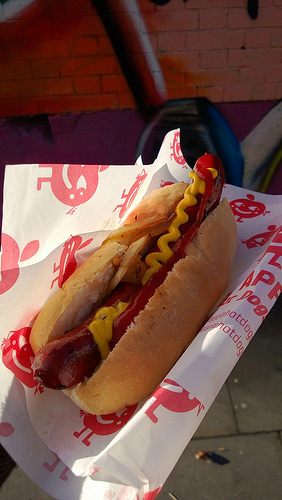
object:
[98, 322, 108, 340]
mustard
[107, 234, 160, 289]
onions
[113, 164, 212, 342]
ketchup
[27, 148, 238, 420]
roll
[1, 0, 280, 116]
wall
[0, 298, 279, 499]
floor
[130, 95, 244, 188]
chair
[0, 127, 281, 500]
paper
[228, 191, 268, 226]
logo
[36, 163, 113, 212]
logo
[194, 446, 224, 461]
leaf